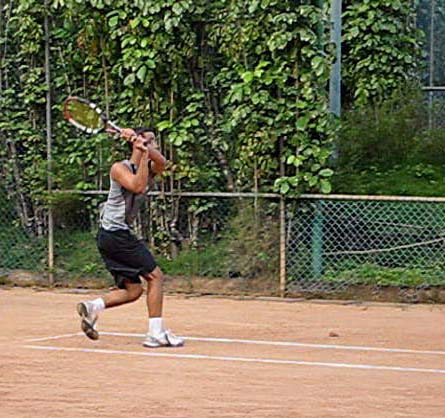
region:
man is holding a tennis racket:
[39, 83, 255, 361]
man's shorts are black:
[82, 196, 169, 293]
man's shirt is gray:
[90, 161, 166, 240]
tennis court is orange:
[0, 279, 432, 412]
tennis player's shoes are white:
[58, 274, 202, 396]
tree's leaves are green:
[0, 0, 441, 203]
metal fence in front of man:
[0, 178, 443, 310]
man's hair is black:
[119, 123, 154, 162]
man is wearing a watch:
[117, 125, 143, 151]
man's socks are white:
[90, 281, 179, 333]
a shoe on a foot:
[143, 333, 183, 347]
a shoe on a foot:
[75, 292, 101, 343]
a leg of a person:
[145, 268, 167, 320]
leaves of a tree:
[221, 46, 267, 120]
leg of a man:
[102, 284, 138, 304]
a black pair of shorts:
[96, 226, 156, 283]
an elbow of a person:
[122, 176, 158, 197]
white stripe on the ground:
[209, 354, 270, 369]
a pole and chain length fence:
[278, 220, 333, 270]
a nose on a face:
[150, 137, 161, 154]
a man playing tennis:
[52, 82, 193, 356]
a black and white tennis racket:
[53, 87, 155, 162]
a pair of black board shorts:
[91, 221, 162, 289]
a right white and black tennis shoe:
[139, 327, 185, 353]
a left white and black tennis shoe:
[71, 298, 100, 343]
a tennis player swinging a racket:
[56, 87, 195, 356]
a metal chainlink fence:
[0, 183, 444, 300]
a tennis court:
[2, 288, 443, 416]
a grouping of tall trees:
[3, 3, 330, 243]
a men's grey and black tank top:
[94, 159, 151, 235]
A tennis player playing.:
[56, 83, 214, 361]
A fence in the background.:
[244, 186, 442, 309]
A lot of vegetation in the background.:
[177, 3, 318, 152]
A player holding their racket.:
[36, 86, 196, 361]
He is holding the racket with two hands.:
[35, 86, 201, 361]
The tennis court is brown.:
[26, 361, 417, 413]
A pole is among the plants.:
[308, 1, 356, 189]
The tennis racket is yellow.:
[41, 92, 117, 150]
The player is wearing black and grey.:
[42, 81, 202, 370]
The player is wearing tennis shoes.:
[36, 80, 204, 363]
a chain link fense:
[11, 185, 440, 280]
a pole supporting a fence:
[277, 146, 293, 291]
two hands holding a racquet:
[58, 90, 148, 148]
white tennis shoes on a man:
[74, 294, 184, 350]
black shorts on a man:
[89, 219, 165, 292]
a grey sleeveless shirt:
[100, 155, 156, 235]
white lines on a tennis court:
[21, 318, 441, 374]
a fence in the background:
[412, 84, 444, 133]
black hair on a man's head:
[123, 123, 154, 145]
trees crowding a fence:
[6, 1, 323, 189]